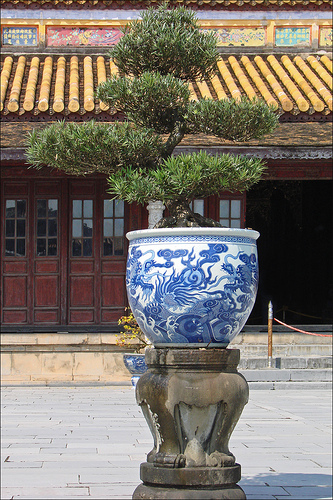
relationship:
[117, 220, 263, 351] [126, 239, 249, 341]
plater has asian motif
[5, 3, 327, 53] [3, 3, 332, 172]
decoration on roof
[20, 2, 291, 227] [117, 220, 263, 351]
plant in vase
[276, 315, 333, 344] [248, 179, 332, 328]
rope blocking entrance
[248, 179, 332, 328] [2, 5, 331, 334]
entrance of a oriental building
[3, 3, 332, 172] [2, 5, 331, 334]
roof of a oriental building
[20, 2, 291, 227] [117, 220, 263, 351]
plant in a pot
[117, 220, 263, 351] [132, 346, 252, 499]
pot on a statue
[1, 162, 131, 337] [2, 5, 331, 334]
doors of a building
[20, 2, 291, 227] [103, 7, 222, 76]
plant has green leaves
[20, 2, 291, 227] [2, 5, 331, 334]
plant in front of building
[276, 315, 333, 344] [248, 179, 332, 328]
rope on entrance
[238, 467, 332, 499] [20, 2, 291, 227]
shadow from tree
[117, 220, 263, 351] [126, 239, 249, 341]
pot with blue dragon